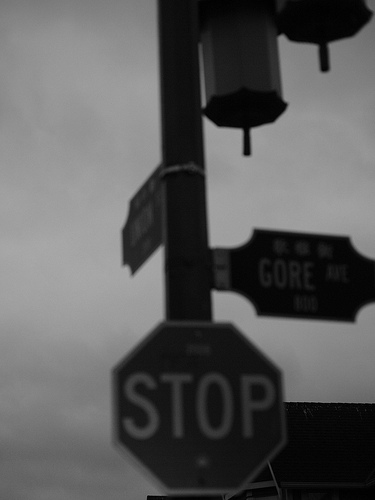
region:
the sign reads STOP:
[116, 366, 276, 450]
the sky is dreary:
[39, 249, 77, 414]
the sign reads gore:
[246, 248, 350, 291]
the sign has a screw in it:
[190, 450, 214, 476]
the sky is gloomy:
[300, 131, 350, 186]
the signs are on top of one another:
[90, 153, 370, 495]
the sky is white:
[17, 378, 74, 474]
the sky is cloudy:
[290, 333, 355, 379]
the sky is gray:
[225, 186, 330, 210]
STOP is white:
[122, 371, 278, 441]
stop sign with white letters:
[108, 313, 309, 490]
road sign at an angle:
[86, 150, 202, 283]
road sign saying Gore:
[204, 196, 373, 331]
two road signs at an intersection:
[59, 128, 372, 370]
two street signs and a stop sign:
[75, 137, 365, 482]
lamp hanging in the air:
[231, 3, 332, 219]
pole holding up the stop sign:
[134, 5, 267, 455]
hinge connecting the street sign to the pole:
[162, 222, 238, 309]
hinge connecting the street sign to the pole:
[94, 147, 220, 270]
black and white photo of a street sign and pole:
[4, 2, 372, 410]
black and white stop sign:
[129, 321, 276, 498]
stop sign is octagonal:
[90, 309, 291, 486]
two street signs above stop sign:
[88, 153, 373, 319]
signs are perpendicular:
[92, 171, 364, 331]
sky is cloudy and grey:
[6, 233, 91, 498]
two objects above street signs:
[210, 2, 357, 165]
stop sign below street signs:
[102, 332, 280, 454]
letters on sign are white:
[122, 357, 277, 458]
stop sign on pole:
[150, 102, 231, 313]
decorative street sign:
[233, 207, 360, 314]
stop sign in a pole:
[107, 319, 288, 483]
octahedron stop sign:
[108, 318, 288, 484]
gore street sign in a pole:
[222, 221, 374, 320]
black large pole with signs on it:
[152, 1, 217, 321]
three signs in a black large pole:
[115, 166, 373, 498]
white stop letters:
[123, 367, 271, 442]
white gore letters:
[255, 253, 316, 291]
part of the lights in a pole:
[198, 3, 288, 130]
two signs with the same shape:
[118, 163, 374, 331]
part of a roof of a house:
[249, 401, 374, 491]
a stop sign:
[104, 338, 228, 487]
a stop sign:
[182, 386, 225, 485]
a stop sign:
[128, 335, 190, 421]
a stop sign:
[157, 317, 243, 490]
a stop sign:
[165, 359, 216, 466]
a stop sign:
[187, 369, 258, 490]